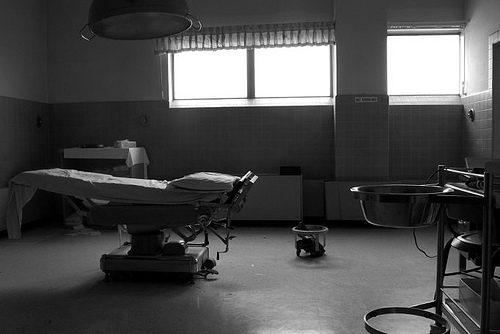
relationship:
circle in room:
[99, 5, 204, 42] [14, 46, 149, 117]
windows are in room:
[171, 39, 350, 111] [14, 46, 149, 117]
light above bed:
[105, 3, 126, 11] [23, 162, 223, 210]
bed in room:
[23, 162, 223, 210] [14, 46, 149, 117]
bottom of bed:
[111, 206, 159, 233] [23, 162, 223, 210]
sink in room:
[348, 182, 422, 226] [14, 46, 149, 117]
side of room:
[36, 78, 77, 116] [14, 46, 149, 117]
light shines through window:
[105, 3, 126, 11] [258, 51, 324, 89]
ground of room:
[274, 289, 319, 313] [14, 46, 149, 117]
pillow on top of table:
[191, 169, 230, 182] [115, 177, 155, 187]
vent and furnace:
[287, 169, 303, 177] [94, 41, 96, 44]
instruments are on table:
[445, 164, 467, 188] [115, 177, 155, 187]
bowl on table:
[92, 136, 127, 151] [115, 177, 155, 187]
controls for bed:
[167, 220, 220, 236] [23, 162, 223, 210]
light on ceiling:
[105, 3, 126, 11] [8, 1, 41, 22]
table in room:
[115, 177, 155, 187] [14, 46, 149, 117]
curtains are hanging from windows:
[239, 28, 274, 49] [171, 39, 350, 111]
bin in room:
[280, 225, 333, 255] [14, 46, 149, 117]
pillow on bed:
[191, 169, 230, 182] [23, 162, 223, 210]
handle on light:
[69, 17, 95, 45] [105, 3, 126, 11]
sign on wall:
[356, 93, 382, 105] [46, 19, 67, 29]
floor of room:
[26, 247, 64, 268] [14, 46, 149, 117]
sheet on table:
[87, 170, 138, 187] [115, 177, 155, 187]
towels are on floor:
[65, 212, 94, 227] [26, 247, 64, 268]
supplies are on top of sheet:
[154, 165, 203, 188] [87, 170, 138, 187]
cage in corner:
[442, 274, 479, 313] [445, 208, 459, 221]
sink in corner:
[348, 182, 422, 226] [445, 208, 459, 221]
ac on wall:
[22, 106, 48, 125] [46, 19, 67, 29]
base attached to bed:
[140, 231, 170, 275] [23, 162, 223, 210]